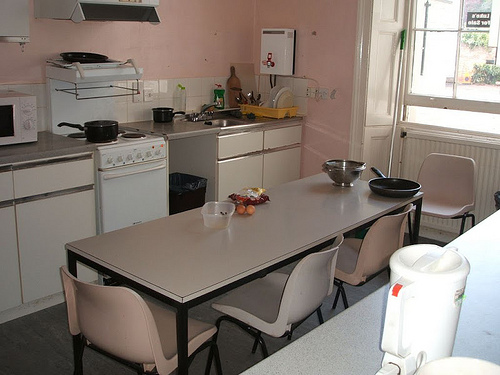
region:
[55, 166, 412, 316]
a long beige rectangle table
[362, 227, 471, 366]
a white pitcher on the counter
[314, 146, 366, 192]
a rounded silver colander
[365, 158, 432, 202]
a black nonstick pan with a black handle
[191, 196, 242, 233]
a clear plastic food storage container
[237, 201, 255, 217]
two oranges on the table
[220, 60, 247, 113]
an amber brown empty bottle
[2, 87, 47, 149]
a small white microwave with turning knobs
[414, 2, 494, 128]
a white framed kitchen window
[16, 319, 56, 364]
a gray slatted kitchen floor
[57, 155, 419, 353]
kitchen table in middle of kitchen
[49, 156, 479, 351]
kitchen table has four chairs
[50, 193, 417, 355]
three chairs are pulled up under table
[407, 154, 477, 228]
one chair under window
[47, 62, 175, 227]
white stove and oven combo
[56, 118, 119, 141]
black pan on stove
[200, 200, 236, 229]
platic container on table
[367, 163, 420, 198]
black frying pan on table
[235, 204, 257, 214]
two oranges on table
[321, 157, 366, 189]
silver bowl on table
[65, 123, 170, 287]
white range with six knobs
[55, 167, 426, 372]
rectangular beige dining table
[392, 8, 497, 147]
window cracked slightly open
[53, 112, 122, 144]
black pot on stove top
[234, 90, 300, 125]
yellow dish drainer with dishes in it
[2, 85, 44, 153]
white microwave on counter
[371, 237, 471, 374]
white drink pitcher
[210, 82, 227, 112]
bottle of green dish detergent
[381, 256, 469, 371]
big white electric kettle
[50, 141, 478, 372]
four plastic chairs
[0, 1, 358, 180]
two walls painted pink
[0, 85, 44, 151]
a white microwave sits on counter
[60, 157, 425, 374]
a black frying pan sits on table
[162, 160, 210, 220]
a black trash can with gray liner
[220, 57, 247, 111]
a wooden cutting board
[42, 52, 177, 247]
a white electric stove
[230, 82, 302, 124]
dishes in plastic yellow rack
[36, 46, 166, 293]
a pan sitting on stove burner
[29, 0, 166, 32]
overhead stove vent